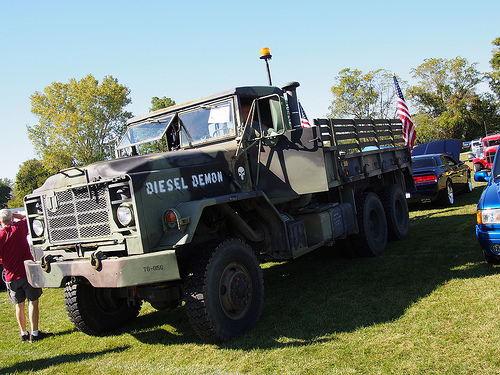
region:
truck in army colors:
[31, 84, 459, 348]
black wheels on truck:
[166, 227, 286, 349]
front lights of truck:
[24, 177, 208, 282]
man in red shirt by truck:
[0, 199, 52, 350]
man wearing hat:
[3, 180, 83, 357]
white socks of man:
[10, 319, 77, 348]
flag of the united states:
[375, 74, 429, 159]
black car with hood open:
[400, 127, 475, 227]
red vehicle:
[457, 127, 498, 182]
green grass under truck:
[158, 256, 446, 365]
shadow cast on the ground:
[144, 304, 424, 356]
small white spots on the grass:
[400, 340, 432, 359]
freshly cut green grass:
[70, 325, 259, 374]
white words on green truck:
[134, 158, 269, 200]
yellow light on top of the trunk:
[241, 33, 312, 72]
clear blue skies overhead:
[78, 17, 188, 54]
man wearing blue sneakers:
[12, 321, 72, 348]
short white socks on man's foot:
[10, 319, 50, 336]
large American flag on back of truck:
[366, 52, 433, 187]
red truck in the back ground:
[449, 125, 499, 172]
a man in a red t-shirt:
[0, 208, 47, 342]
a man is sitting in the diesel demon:
[237, 103, 277, 138]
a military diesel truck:
[22, 80, 412, 339]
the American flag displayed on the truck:
[392, 71, 417, 166]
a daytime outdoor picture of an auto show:
[0, 1, 499, 374]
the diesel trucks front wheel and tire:
[182, 236, 265, 343]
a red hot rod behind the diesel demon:
[470, 133, 496, 173]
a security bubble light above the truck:
[260, 45, 272, 85]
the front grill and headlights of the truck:
[20, 181, 132, 246]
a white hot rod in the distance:
[467, 140, 482, 161]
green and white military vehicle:
[97, 94, 422, 313]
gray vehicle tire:
[204, 242, 269, 337]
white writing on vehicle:
[143, 167, 226, 199]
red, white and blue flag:
[385, 67, 420, 147]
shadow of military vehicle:
[417, 212, 462, 311]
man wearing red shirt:
[6, 224, 26, 264]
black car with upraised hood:
[421, 135, 469, 207]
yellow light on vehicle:
[261, 47, 284, 69]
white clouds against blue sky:
[21, 16, 478, 38]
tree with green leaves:
[10, 55, 110, 152]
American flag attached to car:
[377, 63, 433, 177]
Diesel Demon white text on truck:
[138, 155, 238, 205]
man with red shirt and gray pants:
[6, 206, 65, 327]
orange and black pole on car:
[248, 21, 292, 99]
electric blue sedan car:
[462, 147, 492, 241]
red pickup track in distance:
[457, 116, 497, 173]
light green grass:
[354, 338, 481, 351]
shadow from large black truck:
[263, 243, 448, 339]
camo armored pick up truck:
[59, 90, 430, 294]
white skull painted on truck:
[228, 157, 259, 198]